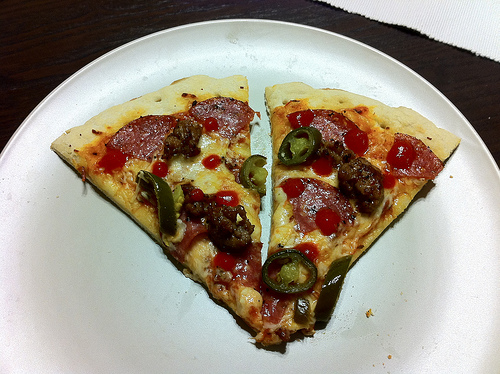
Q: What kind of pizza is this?
A: Pepperoni.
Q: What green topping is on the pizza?
A: Hot peppers.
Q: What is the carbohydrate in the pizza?
A: Crust.